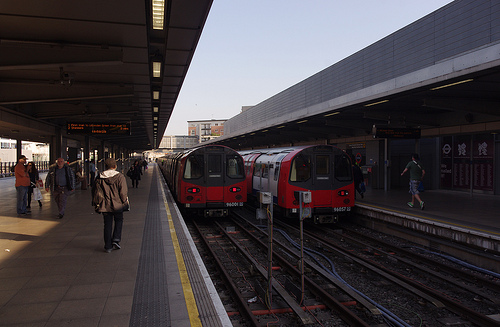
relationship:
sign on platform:
[55, 115, 140, 140] [1, 117, 234, 325]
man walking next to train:
[401, 152, 425, 211] [235, 148, 357, 225]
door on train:
[192, 133, 241, 207] [162, 133, 253, 218]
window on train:
[307, 159, 336, 186] [147, 142, 366, 227]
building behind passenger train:
[189, 115, 228, 145] [157, 145, 247, 218]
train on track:
[244, 141, 359, 226] [199, 210, 358, 326]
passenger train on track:
[157, 145, 247, 218] [309, 216, 496, 316]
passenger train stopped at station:
[157, 145, 247, 218] [1, 2, 498, 324]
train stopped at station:
[236, 141, 354, 224] [1, 2, 498, 324]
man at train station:
[91, 158, 131, 253] [6, 126, 225, 324]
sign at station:
[66, 118, 131, 135] [204, 10, 498, 255]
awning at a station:
[4, 4, 188, 163] [0, 0, 500, 327]